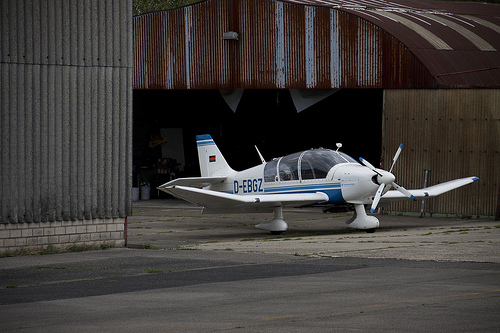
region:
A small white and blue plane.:
[157, 132, 479, 234]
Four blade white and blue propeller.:
[356, 142, 416, 214]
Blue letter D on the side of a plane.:
[232, 179, 239, 193]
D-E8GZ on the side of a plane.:
[231, 177, 263, 193]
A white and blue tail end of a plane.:
[192, 132, 235, 176]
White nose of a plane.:
[375, 170, 393, 186]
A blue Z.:
[255, 178, 265, 193]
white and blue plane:
[160, 108, 414, 200]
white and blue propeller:
[354, 161, 428, 186]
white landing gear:
[254, 200, 401, 255]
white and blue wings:
[165, 164, 487, 216]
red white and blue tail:
[187, 130, 225, 180]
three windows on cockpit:
[241, 138, 361, 205]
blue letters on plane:
[221, 168, 285, 213]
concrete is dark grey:
[192, 271, 299, 328]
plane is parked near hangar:
[111, 134, 402, 241]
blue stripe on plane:
[204, 184, 358, 205]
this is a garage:
[51, 28, 444, 303]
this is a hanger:
[70, 22, 420, 309]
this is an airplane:
[190, 117, 390, 252]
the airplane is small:
[180, 115, 456, 274]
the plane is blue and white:
[224, 121, 459, 254]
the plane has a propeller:
[357, 146, 434, 220]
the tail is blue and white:
[187, 130, 256, 192]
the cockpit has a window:
[256, 145, 336, 180]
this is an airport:
[55, 240, 450, 307]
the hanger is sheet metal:
[50, 78, 112, 184]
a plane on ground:
[148, 123, 483, 241]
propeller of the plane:
[356, 140, 420, 216]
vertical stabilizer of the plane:
[187, 130, 236, 172]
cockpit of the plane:
[298, 145, 355, 182]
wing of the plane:
[158, 182, 325, 217]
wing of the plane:
[388, 173, 480, 202]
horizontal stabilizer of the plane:
[157, 173, 227, 190]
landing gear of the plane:
[346, 215, 384, 236]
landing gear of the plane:
[253, 214, 293, 237]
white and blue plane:
[151, 130, 485, 239]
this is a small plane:
[143, 100, 492, 263]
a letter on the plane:
[226, 175, 243, 196]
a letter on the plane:
[237, 178, 248, 197]